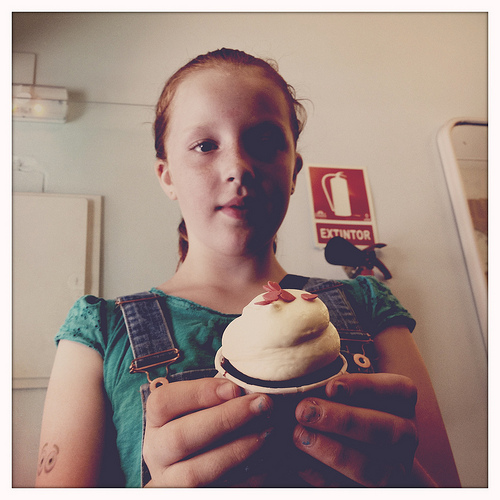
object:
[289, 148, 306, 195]
ear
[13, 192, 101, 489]
freezer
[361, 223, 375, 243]
white letter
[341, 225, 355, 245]
white letter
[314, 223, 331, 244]
white letter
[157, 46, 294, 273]
head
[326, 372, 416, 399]
finger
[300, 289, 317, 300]
chip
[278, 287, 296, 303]
chip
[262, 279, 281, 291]
chip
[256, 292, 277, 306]
chip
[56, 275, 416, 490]
shirt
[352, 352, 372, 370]
button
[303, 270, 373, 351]
strap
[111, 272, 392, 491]
overalls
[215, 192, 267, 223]
lips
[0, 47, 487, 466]
wall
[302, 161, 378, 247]
sign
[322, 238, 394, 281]
extinguisher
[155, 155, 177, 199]
ear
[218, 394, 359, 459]
polish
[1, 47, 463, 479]
girl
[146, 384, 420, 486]
two hands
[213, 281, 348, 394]
cupcake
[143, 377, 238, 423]
finger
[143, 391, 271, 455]
finger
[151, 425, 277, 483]
finger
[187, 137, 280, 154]
dark eyes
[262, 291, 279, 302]
decoration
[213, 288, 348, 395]
cake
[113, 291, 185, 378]
strap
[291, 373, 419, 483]
fingers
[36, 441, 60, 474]
doodle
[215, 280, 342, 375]
frosting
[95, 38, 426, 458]
girl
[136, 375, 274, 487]
hand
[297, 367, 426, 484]
hand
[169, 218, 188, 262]
ponytail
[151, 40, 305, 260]
hair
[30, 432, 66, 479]
tattoo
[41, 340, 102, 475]
arm